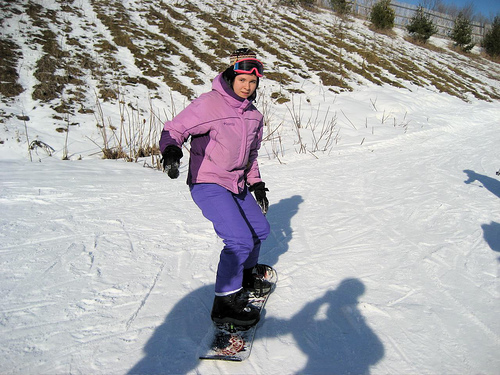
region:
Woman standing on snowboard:
[152, 43, 286, 366]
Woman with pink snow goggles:
[218, 51, 266, 102]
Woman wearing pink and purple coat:
[157, 51, 281, 192]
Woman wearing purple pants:
[173, 51, 276, 298]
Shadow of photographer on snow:
[287, 268, 383, 372]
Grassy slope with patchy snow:
[5, 3, 192, 95]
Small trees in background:
[366, 2, 496, 54]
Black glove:
[157, 140, 187, 183]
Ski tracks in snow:
[5, 182, 182, 374]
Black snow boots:
[210, 269, 276, 326]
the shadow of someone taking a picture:
[292, 273, 387, 374]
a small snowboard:
[199, 256, 279, 368]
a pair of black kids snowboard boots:
[211, 263, 271, 326]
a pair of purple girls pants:
[188, 175, 271, 295]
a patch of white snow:
[326, 162, 445, 257]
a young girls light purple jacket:
[162, 78, 265, 193]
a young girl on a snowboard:
[150, 43, 280, 361]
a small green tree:
[406, 8, 434, 41]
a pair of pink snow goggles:
[231, 57, 263, 76]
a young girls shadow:
[252, 192, 304, 257]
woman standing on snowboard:
[162, 41, 295, 362]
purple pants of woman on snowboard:
[201, 191, 276, 301]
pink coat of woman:
[153, 87, 275, 195]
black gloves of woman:
[164, 150, 271, 218]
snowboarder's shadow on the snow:
[247, 176, 306, 271]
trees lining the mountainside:
[332, 3, 496, 50]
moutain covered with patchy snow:
[7, 2, 459, 136]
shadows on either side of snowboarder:
[121, 281, 396, 371]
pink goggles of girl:
[231, 51, 266, 85]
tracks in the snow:
[26, 178, 496, 355]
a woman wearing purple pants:
[144, 20, 301, 374]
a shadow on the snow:
[294, 270, 378, 373]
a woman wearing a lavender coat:
[146, 44, 302, 367]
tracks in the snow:
[46, 211, 139, 312]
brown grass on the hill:
[303, 20, 461, 102]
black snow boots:
[214, 290, 255, 324]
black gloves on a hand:
[161, 145, 188, 186]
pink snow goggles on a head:
[234, 47, 275, 78]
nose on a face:
[243, 83, 251, 88]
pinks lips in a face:
[240, 87, 251, 97]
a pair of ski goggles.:
[226, 51, 263, 74]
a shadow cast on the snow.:
[285, 272, 387, 373]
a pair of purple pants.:
[181, 182, 276, 293]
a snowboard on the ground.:
[195, 260, 285, 370]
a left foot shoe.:
[238, 263, 287, 308]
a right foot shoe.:
[205, 293, 268, 329]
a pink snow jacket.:
[158, 77, 268, 198]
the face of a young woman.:
[232, 70, 264, 100]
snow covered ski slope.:
[3, 113, 498, 373]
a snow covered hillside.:
[2, 0, 498, 170]